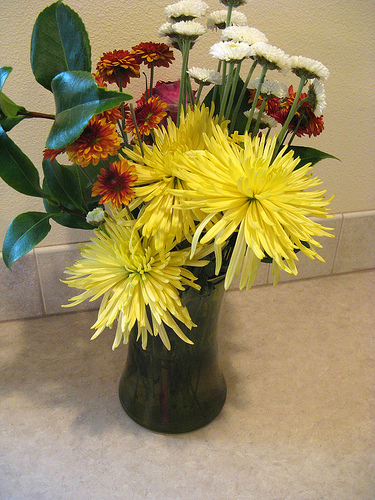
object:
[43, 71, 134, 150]
leaf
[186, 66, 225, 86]
flower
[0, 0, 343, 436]
floral arrangement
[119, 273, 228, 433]
glass vase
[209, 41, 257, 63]
flower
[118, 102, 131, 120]
flower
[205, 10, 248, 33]
flower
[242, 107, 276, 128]
flower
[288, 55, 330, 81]
flower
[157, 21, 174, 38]
flower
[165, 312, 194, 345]
petals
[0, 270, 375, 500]
ground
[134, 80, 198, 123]
flower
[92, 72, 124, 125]
flower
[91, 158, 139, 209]
flower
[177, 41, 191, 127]
green stem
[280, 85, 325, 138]
flower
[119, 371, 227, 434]
vase bottom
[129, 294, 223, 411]
flower stems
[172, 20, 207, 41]
flower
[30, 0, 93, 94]
leaves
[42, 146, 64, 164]
flower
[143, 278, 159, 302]
petal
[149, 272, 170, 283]
petal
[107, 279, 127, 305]
petal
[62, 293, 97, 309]
petal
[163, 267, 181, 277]
petal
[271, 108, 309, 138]
flower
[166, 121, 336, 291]
cattle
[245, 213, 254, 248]
petal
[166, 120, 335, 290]
petal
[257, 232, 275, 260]
petal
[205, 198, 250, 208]
petal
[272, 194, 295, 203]
petal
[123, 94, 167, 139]
flower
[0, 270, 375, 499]
floor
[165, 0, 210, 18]
flower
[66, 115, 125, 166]
flower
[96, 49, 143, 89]
flower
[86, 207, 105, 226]
flower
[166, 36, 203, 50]
flower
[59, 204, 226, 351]
flower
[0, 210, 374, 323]
tiles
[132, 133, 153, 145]
flower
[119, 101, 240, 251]
flower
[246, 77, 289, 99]
flower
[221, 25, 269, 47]
flower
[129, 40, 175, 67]
flower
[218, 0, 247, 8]
flower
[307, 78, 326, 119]
flower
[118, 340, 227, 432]
water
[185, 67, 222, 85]
petal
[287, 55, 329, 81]
petal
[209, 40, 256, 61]
petal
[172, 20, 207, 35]
petal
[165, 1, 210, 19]
petal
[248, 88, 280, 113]
flower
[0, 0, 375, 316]
lower wall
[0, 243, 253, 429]
shadow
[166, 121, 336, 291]
flower